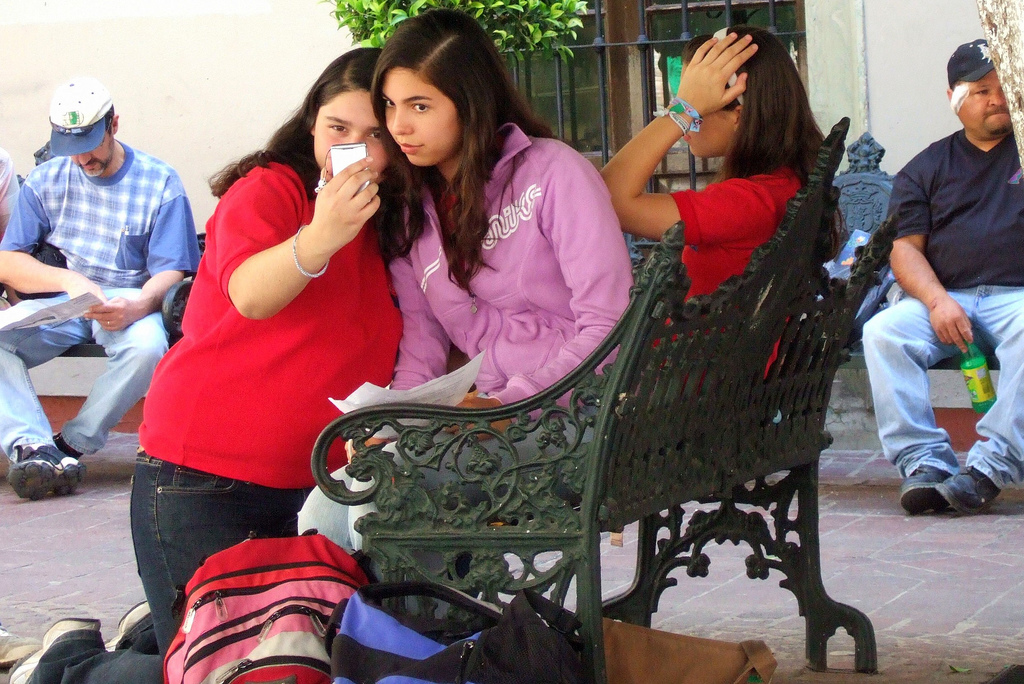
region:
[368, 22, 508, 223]
the head of a girl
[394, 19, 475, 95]
the hair of a girl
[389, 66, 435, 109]
the forehead of a girl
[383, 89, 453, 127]
the eyes of a girl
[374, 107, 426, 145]
the nose of a girl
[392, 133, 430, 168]
the mouth of a girl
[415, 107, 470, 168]
the cheek of a girl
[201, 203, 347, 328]
the arm of a girl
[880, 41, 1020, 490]
a person is sitting down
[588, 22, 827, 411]
a person is sitting down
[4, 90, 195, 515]
a person is sitting down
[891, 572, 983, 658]
a stone in the floor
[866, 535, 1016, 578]
a stone in the floor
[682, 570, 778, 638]
a stone in the floor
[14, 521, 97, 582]
a stone in the floor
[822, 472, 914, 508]
a stone in the floor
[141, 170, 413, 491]
woman wearing a red shirt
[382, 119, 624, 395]
woman wearing a purple shirt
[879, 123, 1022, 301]
man wearing a blue shirt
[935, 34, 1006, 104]
man wearing a blue hat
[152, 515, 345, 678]
backpack on the ground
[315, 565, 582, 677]
backpack on the ground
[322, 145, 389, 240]
girl holding a cellphone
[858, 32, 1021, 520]
A man sitting outside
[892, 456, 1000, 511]
Shoes on a man's feet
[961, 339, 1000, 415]
A drink bottle in a man's hand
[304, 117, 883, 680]
A metal bench outside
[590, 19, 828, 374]
A girl sitting on a bench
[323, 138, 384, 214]
A cell phone in a girl's hand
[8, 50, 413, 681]
A girl kneeling on the ground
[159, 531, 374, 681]
A bag sitting on the ground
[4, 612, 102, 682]
A shoe on a girl's foot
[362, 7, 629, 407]
A girl sitting on a bench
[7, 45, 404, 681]
A girl kneeling outside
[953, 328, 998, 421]
A green and yellow drink bottle in his hand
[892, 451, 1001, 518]
Shoes on a man's foot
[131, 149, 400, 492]
A red shirt on a girl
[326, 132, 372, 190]
A phone in a girl's hand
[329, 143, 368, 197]
A rectangular cell phone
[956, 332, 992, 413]
A bottle of soda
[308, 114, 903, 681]
A metal bench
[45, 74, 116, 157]
a blue and white hat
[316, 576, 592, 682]
A blue and black bag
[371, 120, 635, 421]
A purple sweat shirt.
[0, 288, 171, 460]
A pair of jeans.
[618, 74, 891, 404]
a person sitting down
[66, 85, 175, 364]
a person sitting down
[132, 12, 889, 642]
people taking a picture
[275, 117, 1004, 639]
green bench on the ground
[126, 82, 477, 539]
person wearing red shirt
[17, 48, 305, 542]
person with a hat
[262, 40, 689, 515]
person wearing a pink sweater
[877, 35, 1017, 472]
person with a green bottle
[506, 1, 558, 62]
green leaves on the tree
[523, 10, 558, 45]
green leaves on the tree